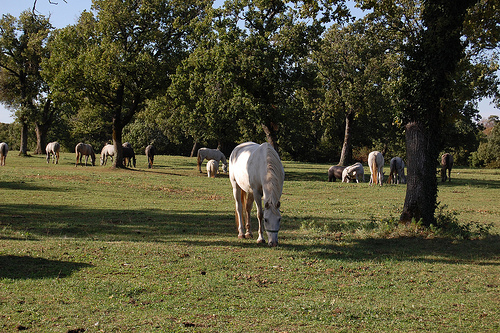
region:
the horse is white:
[225, 139, 286, 248]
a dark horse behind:
[142, 142, 157, 166]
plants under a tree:
[309, 194, 499, 236]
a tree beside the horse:
[335, 0, 492, 229]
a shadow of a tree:
[4, 200, 379, 253]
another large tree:
[49, 0, 156, 190]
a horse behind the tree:
[95, 141, 120, 166]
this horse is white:
[92, 142, 117, 166]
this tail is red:
[369, 149, 380, 186]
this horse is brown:
[435, 149, 456, 187]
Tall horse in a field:
[213, 138, 296, 254]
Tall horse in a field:
[178, 139, 243, 215]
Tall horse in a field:
[138, 138, 165, 180]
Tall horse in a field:
[115, 144, 132, 166]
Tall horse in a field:
[97, 143, 130, 184]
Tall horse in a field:
[66, 135, 98, 176]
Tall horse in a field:
[24, 119, 64, 177]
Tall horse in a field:
[0, 131, 19, 173]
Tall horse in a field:
[345, 139, 397, 194]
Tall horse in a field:
[383, 151, 406, 208]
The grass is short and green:
[27, 203, 171, 291]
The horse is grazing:
[214, 138, 306, 253]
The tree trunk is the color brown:
[378, 1, 470, 224]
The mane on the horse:
[264, 140, 285, 214]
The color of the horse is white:
[218, 119, 298, 241]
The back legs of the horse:
[226, 185, 256, 240]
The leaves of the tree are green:
[57, 30, 132, 107]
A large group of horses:
[0, 122, 469, 249]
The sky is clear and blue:
[5, 0, 101, 29]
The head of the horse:
[259, 198, 289, 248]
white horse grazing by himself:
[218, 139, 293, 259]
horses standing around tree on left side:
[35, 122, 158, 178]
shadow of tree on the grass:
[303, 221, 499, 273]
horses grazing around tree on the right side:
[325, 138, 456, 188]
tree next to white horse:
[334, 1, 490, 206]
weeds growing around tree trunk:
[347, 201, 465, 239]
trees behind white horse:
[4, 6, 469, 166]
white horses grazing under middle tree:
[188, 139, 228, 172]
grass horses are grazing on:
[6, 143, 476, 331]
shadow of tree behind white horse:
[8, 187, 315, 242]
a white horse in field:
[227, 142, 283, 247]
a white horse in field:
[366, 147, 384, 183]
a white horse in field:
[194, 146, 228, 173]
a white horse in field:
[74, 142, 279, 223]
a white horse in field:
[42, 138, 59, 162]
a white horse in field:
[0, 140, 6, 161]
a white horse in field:
[387, 154, 403, 184]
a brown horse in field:
[440, 150, 457, 180]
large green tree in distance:
[296, 22, 405, 165]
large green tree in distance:
[39, 48, 161, 170]